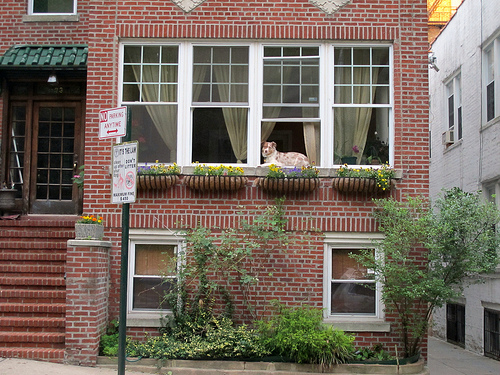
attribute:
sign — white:
[102, 106, 136, 373]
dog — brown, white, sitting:
[262, 139, 307, 167]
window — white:
[263, 56, 320, 168]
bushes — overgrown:
[177, 207, 328, 355]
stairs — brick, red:
[2, 217, 62, 363]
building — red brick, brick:
[6, 9, 430, 369]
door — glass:
[26, 106, 72, 211]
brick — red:
[91, 7, 419, 35]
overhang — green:
[1, 40, 102, 90]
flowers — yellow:
[186, 160, 242, 185]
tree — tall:
[346, 185, 492, 363]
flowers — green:
[152, 309, 377, 363]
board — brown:
[131, 237, 185, 285]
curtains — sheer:
[139, 50, 265, 161]